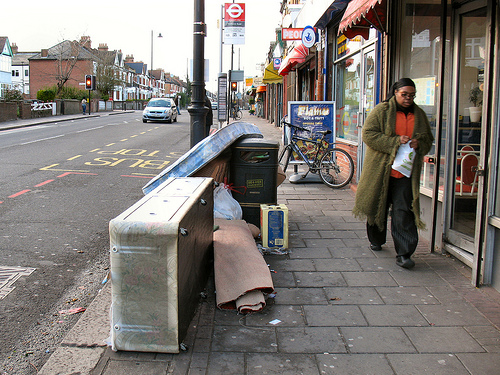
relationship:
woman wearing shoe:
[348, 77, 434, 269] [392, 253, 419, 273]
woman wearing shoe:
[348, 77, 434, 269] [368, 244, 382, 254]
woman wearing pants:
[348, 77, 434, 269] [367, 177, 416, 254]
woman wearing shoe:
[348, 77, 434, 269] [387, 241, 417, 269]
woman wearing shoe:
[348, 77, 434, 269] [365, 240, 385, 252]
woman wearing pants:
[348, 77, 434, 269] [364, 173, 420, 263]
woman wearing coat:
[348, 77, 434, 269] [353, 100, 435, 229]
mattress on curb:
[137, 119, 263, 199] [70, 239, 147, 353]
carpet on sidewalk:
[209, 211, 279, 321] [107, 127, 498, 371]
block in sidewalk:
[240, 351, 322, 375] [292, 182, 498, 372]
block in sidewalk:
[240, 351, 322, 375] [95, 106, 498, 373]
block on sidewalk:
[240, 305, 310, 325] [186, 63, 478, 373]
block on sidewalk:
[450, 352, 500, 375] [186, 63, 478, 373]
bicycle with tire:
[277, 115, 354, 190] [273, 138, 298, 183]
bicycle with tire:
[277, 115, 354, 190] [313, 143, 358, 187]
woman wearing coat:
[338, 65, 439, 275] [355, 102, 432, 256]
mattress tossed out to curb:
[142, 121, 263, 194] [37, 275, 114, 373]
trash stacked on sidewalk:
[259, 202, 292, 253] [95, 106, 498, 373]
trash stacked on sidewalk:
[259, 203, 288, 249] [95, 106, 498, 373]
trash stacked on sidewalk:
[103, 170, 216, 353] [95, 106, 498, 373]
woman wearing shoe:
[348, 77, 434, 269] [392, 249, 416, 270]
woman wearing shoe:
[348, 77, 434, 269] [391, 254, 413, 267]